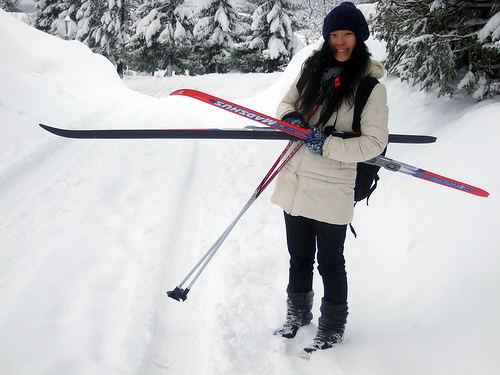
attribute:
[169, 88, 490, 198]
ski — red 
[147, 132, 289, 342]
poles — black , ski  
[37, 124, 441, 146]
ski — black 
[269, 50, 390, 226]
jacket — white 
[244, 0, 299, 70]
tree — with snow on it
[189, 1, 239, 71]
tree — with snow on it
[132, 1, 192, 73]
tree — with snow on it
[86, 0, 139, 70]
tree — with snow on it